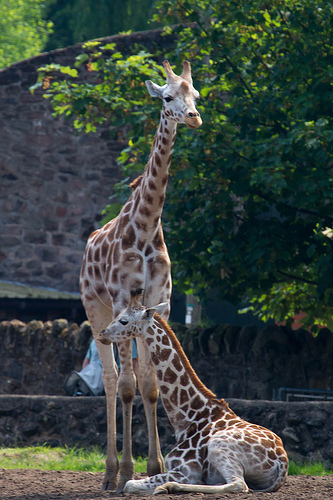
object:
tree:
[26, 0, 333, 340]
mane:
[152, 311, 216, 401]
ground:
[307, 98, 322, 118]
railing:
[273, 384, 333, 403]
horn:
[161, 59, 174, 80]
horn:
[182, 59, 192, 80]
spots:
[99, 234, 111, 261]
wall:
[1, 17, 206, 297]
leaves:
[223, 114, 324, 290]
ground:
[0, 470, 333, 500]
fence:
[0, 314, 331, 461]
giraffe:
[95, 286, 289, 494]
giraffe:
[78, 58, 204, 495]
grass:
[0, 440, 333, 480]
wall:
[0, 314, 329, 395]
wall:
[0, 395, 332, 464]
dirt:
[1, 468, 331, 498]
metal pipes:
[278, 385, 333, 406]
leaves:
[199, 15, 281, 123]